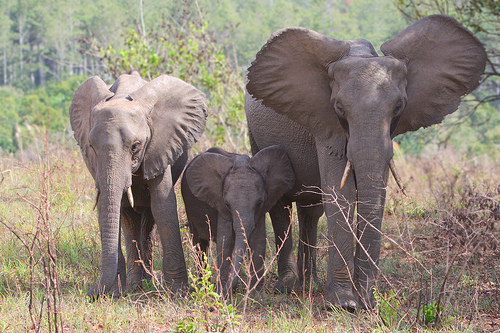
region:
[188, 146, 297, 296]
the baby elephant is in the middle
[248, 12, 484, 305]
the elephant is huge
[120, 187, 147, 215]
the elephant has a tusk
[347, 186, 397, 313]
the elephant has a trunk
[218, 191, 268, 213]
the elephant has eyes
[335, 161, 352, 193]
the elephant has a tusk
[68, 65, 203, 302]
the elephant is standing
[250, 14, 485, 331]
the elephant is gray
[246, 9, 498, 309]
the elephant has big ears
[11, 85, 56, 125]
the green bushes are in the background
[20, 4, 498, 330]
A family of elephants are walking together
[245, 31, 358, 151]
The elephant has large ears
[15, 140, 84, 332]
The weeds are dry and dead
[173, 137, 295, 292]
The baby elephant is looking at the ground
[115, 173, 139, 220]
The elephant has a white tusk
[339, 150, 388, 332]
The elephant has a long trunk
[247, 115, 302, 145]
The elephant is wrinkled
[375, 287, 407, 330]
Clumps of grass in the field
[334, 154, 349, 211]
The elephant has mud on its tusk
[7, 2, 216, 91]
Group of trees in the background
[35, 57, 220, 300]
an elephant in a field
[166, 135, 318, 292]
a small baby elephant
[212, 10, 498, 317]
a large brown elephant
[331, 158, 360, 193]
elephant tusks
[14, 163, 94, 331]
sticks on the ground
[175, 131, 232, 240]
small elephant ear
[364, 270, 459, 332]
weeds growing in the ground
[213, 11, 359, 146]
large elephant ear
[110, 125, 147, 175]
black eye of an elephant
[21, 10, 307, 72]
forest of trees behind the elephants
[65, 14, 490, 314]
looks like mommy, daddy, baby, when it's mom and 2 babies.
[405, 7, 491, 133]
large right ear flappin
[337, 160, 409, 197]
bloody tusks from battle no doubt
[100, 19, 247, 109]
extremely green tree/bush thing behind the midsized elephant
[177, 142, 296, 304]
for real adorbs baby elephant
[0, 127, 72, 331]
extremely dry weed/tree stuck in the ground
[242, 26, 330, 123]
right ear that's not as floppy as the left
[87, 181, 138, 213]
baby tusks growing in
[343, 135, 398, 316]
rather long elephant's trunk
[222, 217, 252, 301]
cute short little baby trunk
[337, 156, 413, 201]
the elphant tusks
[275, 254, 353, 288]
wrinkles on the feet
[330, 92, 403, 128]
the eyes on the elephant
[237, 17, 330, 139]
the ear of the elephant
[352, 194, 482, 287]
the bare branch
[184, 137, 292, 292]
the baby elephant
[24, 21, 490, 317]
three elephants in the brush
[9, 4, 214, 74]
trees behinf the elephants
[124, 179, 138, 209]
the small white tusks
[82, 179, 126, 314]
the trunk on the ground